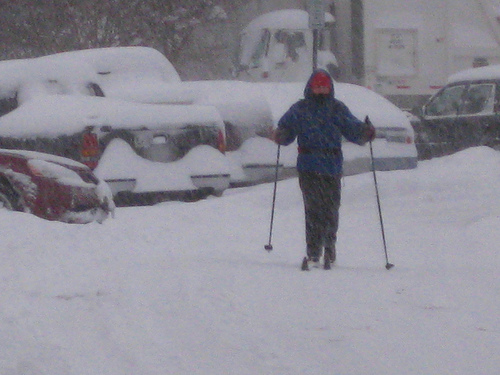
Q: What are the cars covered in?
A: Snow.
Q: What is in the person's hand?
A: Poles.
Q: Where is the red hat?
A: On the person's head.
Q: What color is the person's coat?
A: Blue.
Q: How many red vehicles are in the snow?
A: 1.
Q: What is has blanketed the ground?
A: Snow.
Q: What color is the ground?
A: White.